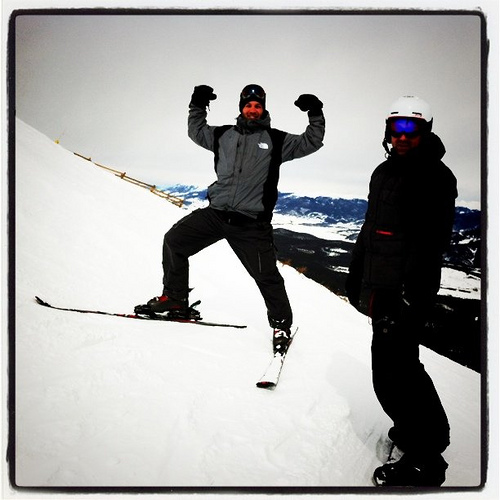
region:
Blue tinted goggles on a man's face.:
[384, 115, 434, 135]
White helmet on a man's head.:
[383, 93, 432, 128]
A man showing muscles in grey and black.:
[133, 83, 327, 353]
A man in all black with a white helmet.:
[346, 95, 456, 485]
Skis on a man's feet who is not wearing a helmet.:
[31, 294, 298, 390]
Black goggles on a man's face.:
[238, 87, 265, 99]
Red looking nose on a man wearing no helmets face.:
[250, 102, 257, 113]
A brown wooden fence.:
[72, 151, 185, 208]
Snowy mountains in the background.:
[165, 178, 487, 268]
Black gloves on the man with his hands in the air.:
[190, 85, 326, 113]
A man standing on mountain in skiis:
[33, 84, 325, 389]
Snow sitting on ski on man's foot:
[257, 318, 299, 389]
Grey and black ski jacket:
[188, 84, 325, 219]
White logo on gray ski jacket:
[257, 141, 269, 149]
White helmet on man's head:
[388, 90, 433, 123]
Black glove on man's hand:
[295, 93, 324, 110]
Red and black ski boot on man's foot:
[133, 294, 192, 322]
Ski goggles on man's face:
[384, 118, 426, 137]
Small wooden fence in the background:
[69, 145, 183, 210]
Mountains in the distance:
[158, 182, 481, 274]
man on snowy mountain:
[20, 83, 320, 410]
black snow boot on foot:
[146, 283, 193, 313]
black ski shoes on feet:
[132, 294, 194, 322]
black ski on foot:
[247, 359, 291, 388]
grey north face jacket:
[192, 125, 282, 214]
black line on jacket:
[260, 125, 287, 214]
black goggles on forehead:
[229, 82, 265, 102]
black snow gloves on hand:
[280, 92, 322, 114]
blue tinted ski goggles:
[386, 115, 426, 132]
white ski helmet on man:
[391, 93, 434, 119]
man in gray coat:
[217, 83, 304, 287]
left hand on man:
[176, 72, 219, 134]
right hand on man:
[284, 90, 338, 165]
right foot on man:
[116, 238, 266, 345]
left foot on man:
[263, 308, 335, 370]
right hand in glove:
[177, 83, 234, 135]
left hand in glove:
[286, 85, 363, 141]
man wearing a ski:
[113, 269, 273, 339]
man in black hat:
[229, 76, 307, 160]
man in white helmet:
[379, 63, 453, 199]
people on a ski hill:
[23, 62, 478, 497]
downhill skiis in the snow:
[28, 288, 302, 400]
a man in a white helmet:
[385, 86, 440, 128]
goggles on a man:
[379, 116, 436, 137]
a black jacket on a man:
[342, 137, 458, 304]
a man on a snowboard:
[359, 296, 458, 497]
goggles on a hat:
[242, 83, 271, 110]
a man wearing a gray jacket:
[186, 94, 329, 216]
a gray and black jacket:
[179, 100, 331, 224]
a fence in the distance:
[70, 143, 188, 206]